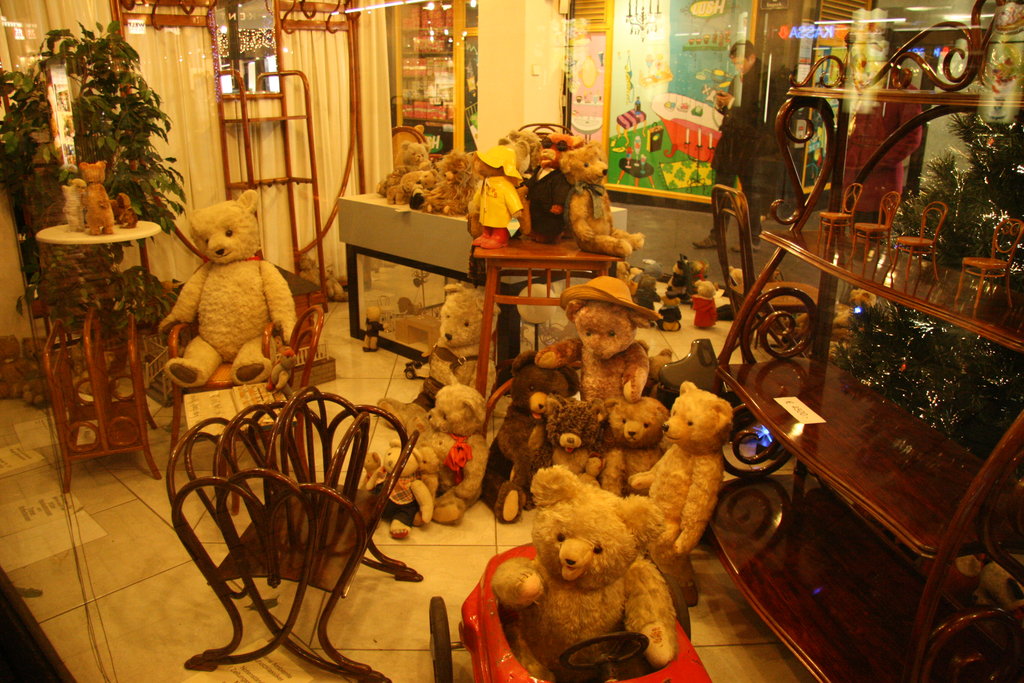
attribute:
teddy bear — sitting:
[144, 180, 300, 399]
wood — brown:
[827, 404, 897, 484]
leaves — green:
[125, 97, 160, 143]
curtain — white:
[278, 7, 395, 286]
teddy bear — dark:
[470, 352, 585, 530]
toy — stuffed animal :
[479, 454, 687, 660]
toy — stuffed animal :
[626, 370, 743, 571]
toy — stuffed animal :
[598, 382, 672, 493]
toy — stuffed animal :
[561, 270, 637, 391]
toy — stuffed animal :
[144, 177, 311, 391]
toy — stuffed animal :
[461, 158, 533, 256]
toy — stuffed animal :
[561, 260, 646, 414]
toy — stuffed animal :
[552, 134, 654, 260]